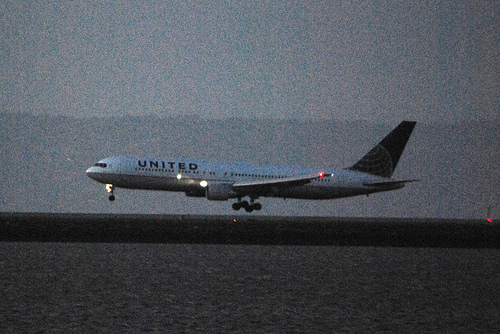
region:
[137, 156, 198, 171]
The word UNITED in black letters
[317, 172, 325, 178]
A red light on the plane.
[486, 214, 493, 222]
A red light on the ground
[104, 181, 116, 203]
The front wheel of the plane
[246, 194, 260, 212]
One of the back landing wheels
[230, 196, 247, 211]
The other back landing wheel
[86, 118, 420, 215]
A primarily white airplane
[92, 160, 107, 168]
The front window of an airplane.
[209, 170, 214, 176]
A passenger window on the airplane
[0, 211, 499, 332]
The ground of the image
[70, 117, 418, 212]
Airplane taking off over water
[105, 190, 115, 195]
Front landing wheel on plane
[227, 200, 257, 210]
Back landing gear on plane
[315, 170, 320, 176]
Red light on plane wing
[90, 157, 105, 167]
Cockpit windows on plane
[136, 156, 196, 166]
Black letters on side of plane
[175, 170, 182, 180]
White light on plane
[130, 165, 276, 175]
Line of passenger windows on plane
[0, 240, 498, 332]
Water underneath flying plane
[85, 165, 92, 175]
nose of the plane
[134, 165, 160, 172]
windows of plane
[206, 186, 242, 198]
engine of plane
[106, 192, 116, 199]
front wheels of plane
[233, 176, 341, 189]
Wing of plane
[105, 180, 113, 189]
White light near landing gear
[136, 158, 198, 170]
UNITED mentioned on body of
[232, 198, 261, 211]
back wheel of plane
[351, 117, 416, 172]
tail wings of plane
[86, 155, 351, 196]
grey and white color plane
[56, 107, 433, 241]
a plane in the air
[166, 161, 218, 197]
lights working in the plane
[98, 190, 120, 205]
front wheel of the plane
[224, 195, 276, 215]
back wheel of the plane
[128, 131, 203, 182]
name of the plane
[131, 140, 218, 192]
name on the plane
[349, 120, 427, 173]
top part of the plane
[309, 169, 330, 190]
red light on the plane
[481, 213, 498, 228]
red light on the top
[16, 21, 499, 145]
a beautiful view of sky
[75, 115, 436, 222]
Plane is flying in air.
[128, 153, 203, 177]
Letters are black color.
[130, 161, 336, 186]
Windows are on sides of the plane.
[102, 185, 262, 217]
Landing gear is black color.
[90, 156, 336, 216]
Lights are on in plane.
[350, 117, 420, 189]
Logo is on the wings.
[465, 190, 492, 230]
Tower is seen in right side of the picture.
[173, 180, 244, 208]
Two engine on the wings.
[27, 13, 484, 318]
Day time picture.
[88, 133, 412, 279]
Plane is flying above the water.